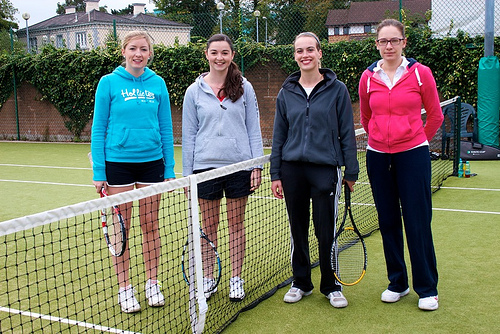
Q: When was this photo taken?
A: During the daytime.